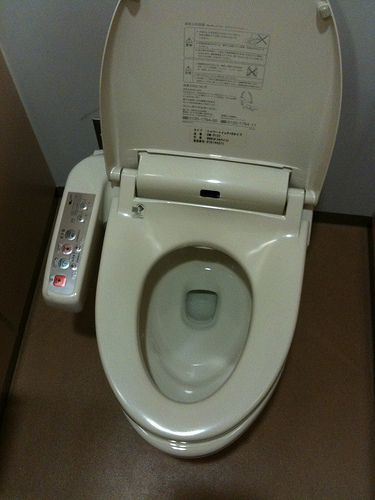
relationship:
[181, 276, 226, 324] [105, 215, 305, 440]
drain in bottom of toilet bowl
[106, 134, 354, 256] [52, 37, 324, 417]
hinge of toilet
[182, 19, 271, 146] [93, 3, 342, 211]
instructions on lid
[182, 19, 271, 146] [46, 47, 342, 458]
instructions on toilet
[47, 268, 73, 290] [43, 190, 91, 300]
button on control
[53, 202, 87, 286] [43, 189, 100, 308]
button over silver support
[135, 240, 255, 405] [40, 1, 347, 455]
water in toilet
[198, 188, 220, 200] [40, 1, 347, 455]
hole on toilet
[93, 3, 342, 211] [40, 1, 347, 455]
lid of toilet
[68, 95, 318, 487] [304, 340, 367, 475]
toilet sitting on floor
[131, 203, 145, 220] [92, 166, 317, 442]
sticker on seat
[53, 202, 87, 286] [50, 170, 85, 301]
button on control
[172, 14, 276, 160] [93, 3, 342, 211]
instructions on lid